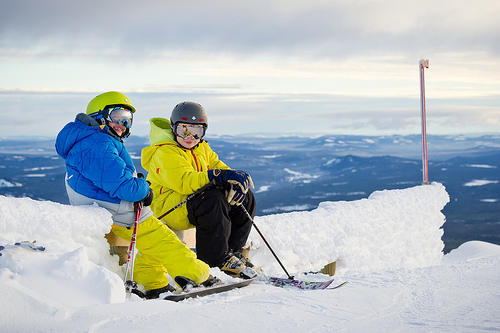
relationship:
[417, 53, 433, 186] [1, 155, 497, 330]
pole on ski slope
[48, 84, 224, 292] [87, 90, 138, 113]
man wearing helmet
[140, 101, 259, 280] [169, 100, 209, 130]
people wearing helmet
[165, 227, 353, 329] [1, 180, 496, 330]
skis on slope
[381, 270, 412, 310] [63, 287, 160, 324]
footprints on snow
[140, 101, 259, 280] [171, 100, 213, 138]
people wearing helmet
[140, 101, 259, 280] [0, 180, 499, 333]
people sitting on snow mound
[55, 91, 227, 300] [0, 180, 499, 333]
child sitting on snow mound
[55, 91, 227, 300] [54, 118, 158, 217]
child wearing jacket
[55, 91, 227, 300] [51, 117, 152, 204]
child wearing jacket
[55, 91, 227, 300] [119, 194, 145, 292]
child resting on ski pole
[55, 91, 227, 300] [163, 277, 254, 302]
child wearing skis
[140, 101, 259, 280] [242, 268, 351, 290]
people wearing skis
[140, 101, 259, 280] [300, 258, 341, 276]
people wearing skis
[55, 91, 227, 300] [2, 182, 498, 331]
child sitting in snow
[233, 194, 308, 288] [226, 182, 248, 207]
ski pole in hand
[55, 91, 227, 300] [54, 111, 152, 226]
child wearing jacket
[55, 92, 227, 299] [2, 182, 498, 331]
child sitting on snow